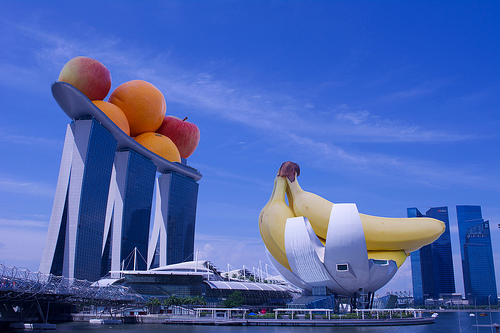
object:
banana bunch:
[259, 160, 447, 278]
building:
[266, 203, 399, 299]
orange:
[107, 78, 168, 136]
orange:
[91, 100, 131, 139]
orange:
[133, 131, 182, 165]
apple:
[57, 56, 111, 104]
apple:
[158, 115, 201, 160]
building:
[402, 203, 455, 309]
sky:
[0, 0, 499, 301]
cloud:
[0, 19, 489, 196]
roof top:
[262, 202, 400, 299]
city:
[0, 81, 498, 322]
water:
[0, 311, 500, 333]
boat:
[429, 311, 439, 318]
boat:
[466, 312, 475, 317]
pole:
[132, 246, 138, 271]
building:
[36, 119, 120, 286]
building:
[102, 146, 157, 282]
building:
[148, 168, 203, 266]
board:
[50, 80, 202, 181]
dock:
[2, 320, 63, 331]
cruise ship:
[87, 246, 290, 309]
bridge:
[0, 265, 147, 320]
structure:
[260, 309, 266, 315]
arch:
[203, 279, 298, 295]